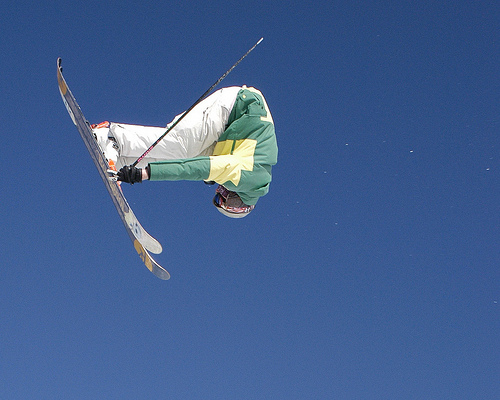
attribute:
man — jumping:
[92, 86, 279, 220]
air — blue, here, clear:
[1, 1, 498, 400]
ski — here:
[55, 57, 164, 255]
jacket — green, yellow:
[151, 89, 278, 204]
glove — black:
[115, 166, 140, 183]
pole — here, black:
[127, 35, 265, 169]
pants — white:
[111, 85, 240, 171]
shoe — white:
[92, 121, 109, 149]